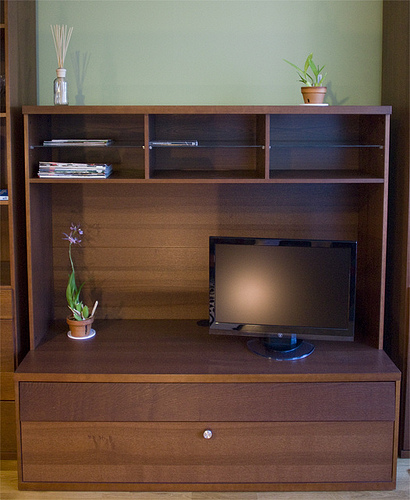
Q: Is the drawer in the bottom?
A: Yes, the drawer is in the bottom of the image.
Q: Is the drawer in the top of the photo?
A: No, the drawer is in the bottom of the image.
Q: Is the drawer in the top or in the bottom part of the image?
A: The drawer is in the bottom of the image.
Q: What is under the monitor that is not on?
A: The drawer is under the monitor.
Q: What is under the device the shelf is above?
A: The drawer is under the monitor.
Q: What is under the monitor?
A: The drawer is under the monitor.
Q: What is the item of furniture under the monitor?
A: The piece of furniture is a drawer.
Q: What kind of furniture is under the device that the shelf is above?
A: The piece of furniture is a drawer.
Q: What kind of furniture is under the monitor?
A: The piece of furniture is a drawer.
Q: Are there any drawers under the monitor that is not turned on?
A: Yes, there is a drawer under the monitor.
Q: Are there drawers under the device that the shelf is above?
A: Yes, there is a drawer under the monitor.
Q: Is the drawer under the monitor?
A: Yes, the drawer is under the monitor.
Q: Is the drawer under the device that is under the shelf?
A: Yes, the drawer is under the monitor.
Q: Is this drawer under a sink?
A: No, the drawer is under the monitor.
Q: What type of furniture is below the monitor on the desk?
A: The piece of furniture is a drawer.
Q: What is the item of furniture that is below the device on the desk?
A: The piece of furniture is a drawer.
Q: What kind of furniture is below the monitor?
A: The piece of furniture is a drawer.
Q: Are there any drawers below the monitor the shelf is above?
A: Yes, there is a drawer below the monitor.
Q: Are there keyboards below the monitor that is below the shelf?
A: No, there is a drawer below the monitor.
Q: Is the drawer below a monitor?
A: Yes, the drawer is below a monitor.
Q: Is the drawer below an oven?
A: No, the drawer is below a monitor.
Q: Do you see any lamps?
A: No, there are no lamps.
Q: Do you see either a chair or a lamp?
A: No, there are no lamps or chairs.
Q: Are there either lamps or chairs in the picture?
A: No, there are no lamps or chairs.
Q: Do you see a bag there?
A: No, there are no bags.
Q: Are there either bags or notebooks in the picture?
A: No, there are no bags or notebooks.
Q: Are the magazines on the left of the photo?
A: Yes, the magazines are on the left of the image.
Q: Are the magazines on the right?
A: No, the magazines are on the left of the image.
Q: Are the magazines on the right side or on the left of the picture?
A: The magazines are on the left of the image.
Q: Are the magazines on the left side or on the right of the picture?
A: The magazines are on the left of the image.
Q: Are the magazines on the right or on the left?
A: The magazines are on the left of the image.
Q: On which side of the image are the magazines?
A: The magazines are on the left of the image.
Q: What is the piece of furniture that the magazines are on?
A: The piece of furniture is a desk.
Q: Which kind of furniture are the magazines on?
A: The magazines are on the desk.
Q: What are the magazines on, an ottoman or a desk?
A: The magazines are on a desk.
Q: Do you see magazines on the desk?
A: Yes, there are magazines on the desk.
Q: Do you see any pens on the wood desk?
A: No, there are magazines on the desk.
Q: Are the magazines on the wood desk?
A: Yes, the magazines are on the desk.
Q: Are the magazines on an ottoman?
A: No, the magazines are on the desk.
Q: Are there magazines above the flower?
A: Yes, there are magazines above the flower.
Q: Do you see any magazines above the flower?
A: Yes, there are magazines above the flower.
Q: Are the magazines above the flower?
A: Yes, the magazines are above the flower.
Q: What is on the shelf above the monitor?
A: The magazines are on the shelf.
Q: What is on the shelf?
A: The magazines are on the shelf.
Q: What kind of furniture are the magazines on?
A: The magazines are on the shelf.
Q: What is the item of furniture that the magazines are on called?
A: The piece of furniture is a shelf.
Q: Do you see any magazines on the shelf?
A: Yes, there are magazines on the shelf.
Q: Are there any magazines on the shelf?
A: Yes, there are magazines on the shelf.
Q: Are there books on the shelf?
A: No, there are magazines on the shelf.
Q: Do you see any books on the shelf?
A: No, there are magazines on the shelf.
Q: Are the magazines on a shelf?
A: Yes, the magazines are on a shelf.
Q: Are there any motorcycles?
A: No, there are no motorcycles.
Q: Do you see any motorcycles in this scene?
A: No, there are no motorcycles.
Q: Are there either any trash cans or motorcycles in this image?
A: No, there are no motorcycles or trash cans.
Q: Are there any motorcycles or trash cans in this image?
A: No, there are no motorcycles or trash cans.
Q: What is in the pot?
A: The flower is in the pot.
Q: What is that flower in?
A: The flower is in the pot.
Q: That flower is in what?
A: The flower is in the pot.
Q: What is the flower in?
A: The flower is in the pot.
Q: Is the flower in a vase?
A: No, the flower is in the pot.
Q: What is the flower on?
A: The flower is on the desk.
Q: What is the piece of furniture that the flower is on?
A: The piece of furniture is a desk.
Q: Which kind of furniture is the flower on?
A: The flower is on the desk.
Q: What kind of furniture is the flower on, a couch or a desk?
A: The flower is on a desk.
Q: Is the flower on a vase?
A: No, the flower is on the desk.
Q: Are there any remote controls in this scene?
A: No, there are no remote controls.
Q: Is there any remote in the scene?
A: No, there are no remote controls.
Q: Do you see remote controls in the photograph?
A: No, there are no remote controls.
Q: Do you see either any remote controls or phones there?
A: No, there are no remote controls or phones.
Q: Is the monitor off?
A: Yes, the monitor is off.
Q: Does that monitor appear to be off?
A: Yes, the monitor is off.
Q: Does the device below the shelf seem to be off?
A: Yes, the monitor is off.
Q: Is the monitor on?
A: No, the monitor is off.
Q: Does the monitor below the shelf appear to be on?
A: No, the monitor is off.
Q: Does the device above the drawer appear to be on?
A: No, the monitor is off.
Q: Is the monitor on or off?
A: The monitor is off.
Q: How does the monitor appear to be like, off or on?
A: The monitor is off.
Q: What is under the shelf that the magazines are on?
A: The monitor is under the shelf.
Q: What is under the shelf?
A: The monitor is under the shelf.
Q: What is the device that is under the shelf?
A: The device is a monitor.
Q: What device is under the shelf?
A: The device is a monitor.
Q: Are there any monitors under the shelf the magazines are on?
A: Yes, there is a monitor under the shelf.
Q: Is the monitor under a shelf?
A: Yes, the monitor is under a shelf.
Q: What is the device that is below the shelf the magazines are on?
A: The device is a monitor.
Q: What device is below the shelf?
A: The device is a monitor.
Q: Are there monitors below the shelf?
A: Yes, there is a monitor below the shelf.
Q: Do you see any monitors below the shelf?
A: Yes, there is a monitor below the shelf.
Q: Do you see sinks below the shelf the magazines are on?
A: No, there is a monitor below the shelf.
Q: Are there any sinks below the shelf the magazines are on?
A: No, there is a monitor below the shelf.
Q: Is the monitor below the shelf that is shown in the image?
A: Yes, the monitor is below the shelf.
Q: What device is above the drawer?
A: The device is a monitor.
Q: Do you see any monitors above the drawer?
A: Yes, there is a monitor above the drawer.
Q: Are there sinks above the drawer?
A: No, there is a monitor above the drawer.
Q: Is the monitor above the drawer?
A: Yes, the monitor is above the drawer.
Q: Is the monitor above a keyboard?
A: No, the monitor is above the drawer.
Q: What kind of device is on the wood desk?
A: The device is a monitor.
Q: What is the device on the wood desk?
A: The device is a monitor.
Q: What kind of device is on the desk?
A: The device is a monitor.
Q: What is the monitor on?
A: The monitor is on the desk.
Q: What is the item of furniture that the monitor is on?
A: The piece of furniture is a desk.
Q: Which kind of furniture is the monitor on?
A: The monitor is on the desk.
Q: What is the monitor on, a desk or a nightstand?
A: The monitor is on a desk.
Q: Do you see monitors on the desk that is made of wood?
A: Yes, there is a monitor on the desk.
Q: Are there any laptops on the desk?
A: No, there is a monitor on the desk.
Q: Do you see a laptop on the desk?
A: No, there is a monitor on the desk.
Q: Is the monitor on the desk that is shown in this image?
A: Yes, the monitor is on the desk.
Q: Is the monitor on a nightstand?
A: No, the monitor is on the desk.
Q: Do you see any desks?
A: Yes, there is a desk.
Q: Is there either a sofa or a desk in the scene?
A: Yes, there is a desk.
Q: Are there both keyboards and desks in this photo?
A: No, there is a desk but no keyboards.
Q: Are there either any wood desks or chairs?
A: Yes, there is a wood desk.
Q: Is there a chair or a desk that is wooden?
A: Yes, the desk is wooden.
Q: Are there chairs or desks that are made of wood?
A: Yes, the desk is made of wood.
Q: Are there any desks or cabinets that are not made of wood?
A: No, there is a desk but it is made of wood.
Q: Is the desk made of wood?
A: Yes, the desk is made of wood.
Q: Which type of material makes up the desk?
A: The desk is made of wood.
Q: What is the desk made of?
A: The desk is made of wood.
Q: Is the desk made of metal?
A: No, the desk is made of wood.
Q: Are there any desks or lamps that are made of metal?
A: No, there is a desk but it is made of wood.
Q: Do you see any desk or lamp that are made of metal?
A: No, there is a desk but it is made of wood.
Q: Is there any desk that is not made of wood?
A: No, there is a desk but it is made of wood.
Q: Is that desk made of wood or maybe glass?
A: The desk is made of wood.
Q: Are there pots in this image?
A: Yes, there is a pot.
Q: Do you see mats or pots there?
A: Yes, there is a pot.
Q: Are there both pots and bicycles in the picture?
A: No, there is a pot but no bicycles.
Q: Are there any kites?
A: No, there are no kites.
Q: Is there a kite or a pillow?
A: No, there are no kites or pillows.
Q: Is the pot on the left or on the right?
A: The pot is on the left of the image.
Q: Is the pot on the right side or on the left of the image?
A: The pot is on the left of the image.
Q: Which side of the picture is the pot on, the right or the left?
A: The pot is on the left of the image.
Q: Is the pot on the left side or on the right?
A: The pot is on the left of the image.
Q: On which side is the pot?
A: The pot is on the left of the image.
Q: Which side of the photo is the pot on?
A: The pot is on the left of the image.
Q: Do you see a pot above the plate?
A: Yes, there is a pot above the plate.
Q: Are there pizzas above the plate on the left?
A: No, there is a pot above the plate.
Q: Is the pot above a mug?
A: No, the pot is above the plate.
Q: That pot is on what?
A: The pot is on the desk.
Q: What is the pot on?
A: The pot is on the desk.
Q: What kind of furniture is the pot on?
A: The pot is on the desk.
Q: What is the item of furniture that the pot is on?
A: The piece of furniture is a desk.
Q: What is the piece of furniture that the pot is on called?
A: The piece of furniture is a desk.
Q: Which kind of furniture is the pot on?
A: The pot is on the desk.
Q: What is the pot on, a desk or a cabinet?
A: The pot is on a desk.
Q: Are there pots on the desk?
A: Yes, there is a pot on the desk.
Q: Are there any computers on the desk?
A: No, there is a pot on the desk.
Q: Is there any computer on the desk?
A: No, there is a pot on the desk.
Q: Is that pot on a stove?
A: No, the pot is on a desk.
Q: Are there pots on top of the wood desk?
A: Yes, there is a pot on top of the desk.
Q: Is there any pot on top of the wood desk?
A: Yes, there is a pot on top of the desk.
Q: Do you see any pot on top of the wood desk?
A: Yes, there is a pot on top of the desk.